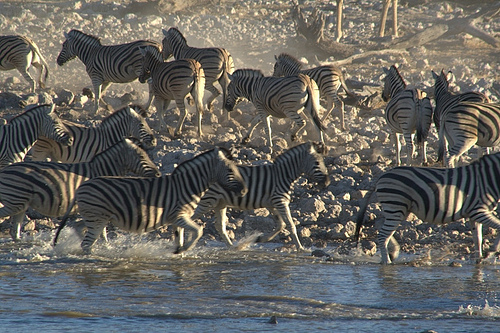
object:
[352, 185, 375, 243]
tail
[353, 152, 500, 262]
zebra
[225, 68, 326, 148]
zebra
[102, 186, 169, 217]
strips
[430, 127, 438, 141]
dry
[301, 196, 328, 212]
rock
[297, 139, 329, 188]
head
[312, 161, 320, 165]
eye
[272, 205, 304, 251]
leg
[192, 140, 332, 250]
zebra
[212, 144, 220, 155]
ear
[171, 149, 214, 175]
mane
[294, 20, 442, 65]
log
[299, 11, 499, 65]
drift wood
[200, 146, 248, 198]
zebra's head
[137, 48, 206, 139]
zebra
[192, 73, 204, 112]
tail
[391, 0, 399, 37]
tree trunk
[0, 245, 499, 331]
river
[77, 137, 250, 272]
zebra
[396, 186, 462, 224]
zebra's belly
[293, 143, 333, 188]
zebra's head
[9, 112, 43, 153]
zebra's neck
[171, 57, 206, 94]
rear end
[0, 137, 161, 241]
zebras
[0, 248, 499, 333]
water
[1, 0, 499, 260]
fields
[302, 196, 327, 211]
rocks